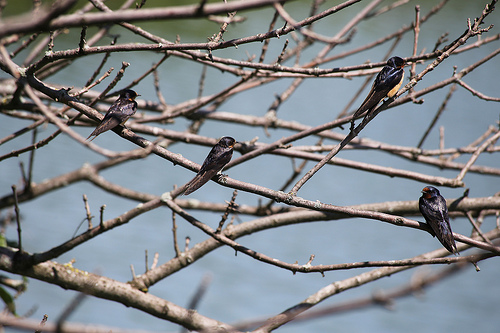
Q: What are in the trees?
A: Birds.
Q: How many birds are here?
A: Four.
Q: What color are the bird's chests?
A: Yellow.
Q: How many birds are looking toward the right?
A: Three.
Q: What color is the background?
A: Grey.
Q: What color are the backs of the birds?
A: Black.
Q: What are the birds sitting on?
A: Branches.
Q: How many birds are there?
A: There are 4.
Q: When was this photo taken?
A: During the afternoon.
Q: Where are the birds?
A: Sitting in a tree without leaves.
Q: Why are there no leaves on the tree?
A: It is winter.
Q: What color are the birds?
A: Black with a tan belly.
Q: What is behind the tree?
A: Water.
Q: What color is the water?
A: Green.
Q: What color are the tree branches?
A: Brown.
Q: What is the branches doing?
A: Crisscrossing one another.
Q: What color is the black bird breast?
A: Orange.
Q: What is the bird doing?
A: Facing the same direction.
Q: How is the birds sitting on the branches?
A: One is higher than the other.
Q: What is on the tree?
A: Various branches.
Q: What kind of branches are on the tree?
A: Long thin branches.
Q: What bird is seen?
A: Sparrow.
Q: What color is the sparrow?
A: Black.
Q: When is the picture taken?
A: Daytime.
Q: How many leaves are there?
A: No leaves.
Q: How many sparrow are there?
A: 4.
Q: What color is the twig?
A: Brown.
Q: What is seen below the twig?
A: Water.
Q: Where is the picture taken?
A: In a tree.